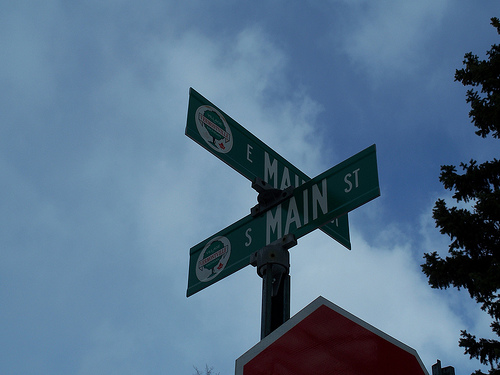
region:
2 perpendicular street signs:
[160, 86, 375, 297]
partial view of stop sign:
[220, 295, 440, 371]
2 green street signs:
[165, 85, 385, 298]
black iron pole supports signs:
[253, 246, 298, 346]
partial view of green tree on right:
[426, 16, 498, 374]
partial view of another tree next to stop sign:
[172, 357, 236, 374]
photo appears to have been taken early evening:
[2, 2, 497, 374]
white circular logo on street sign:
[189, 241, 236, 288]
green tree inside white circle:
[194, 229, 231, 283]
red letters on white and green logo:
[192, 226, 232, 296]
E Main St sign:
[180, 83, 355, 252]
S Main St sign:
[185, 142, 382, 297]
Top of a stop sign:
[231, 292, 437, 373]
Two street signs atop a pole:
[181, 84, 384, 301]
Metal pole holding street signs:
[258, 244, 296, 340]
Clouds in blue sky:
[2, 2, 476, 356]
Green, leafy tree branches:
[420, 12, 497, 374]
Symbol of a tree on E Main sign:
[188, 87, 238, 160]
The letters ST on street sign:
[338, 163, 365, 197]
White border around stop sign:
[226, 292, 431, 372]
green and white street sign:
[181, 84, 382, 296]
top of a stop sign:
[233, 293, 431, 373]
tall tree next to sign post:
[422, 14, 499, 373]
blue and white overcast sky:
[0, 1, 499, 373]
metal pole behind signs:
[248, 247, 292, 339]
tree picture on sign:
[188, 233, 232, 283]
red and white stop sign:
[229, 293, 431, 373]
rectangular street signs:
[163, 80, 380, 298]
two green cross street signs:
[183, 86, 383, 299]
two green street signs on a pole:
[183, 86, 381, 308]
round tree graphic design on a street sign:
[188, 236, 245, 283]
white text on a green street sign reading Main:
[260, 179, 335, 243]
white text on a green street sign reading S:
[235, 223, 256, 250]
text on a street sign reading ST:
[338, 166, 369, 194]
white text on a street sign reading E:
[238, 139, 258, 166]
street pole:
[256, 243, 292, 339]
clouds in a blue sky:
[0, 6, 178, 356]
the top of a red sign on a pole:
[233, 293, 431, 373]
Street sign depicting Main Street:
[175, 84, 441, 374]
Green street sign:
[177, 79, 411, 309]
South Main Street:
[167, 147, 413, 297]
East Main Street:
[167, 57, 394, 256]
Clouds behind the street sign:
[25, 24, 495, 365]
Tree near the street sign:
[388, 11, 494, 373]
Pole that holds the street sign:
[230, 234, 297, 374]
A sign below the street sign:
[195, 284, 495, 374]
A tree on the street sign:
[177, 229, 247, 293]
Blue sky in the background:
[12, 16, 499, 334]